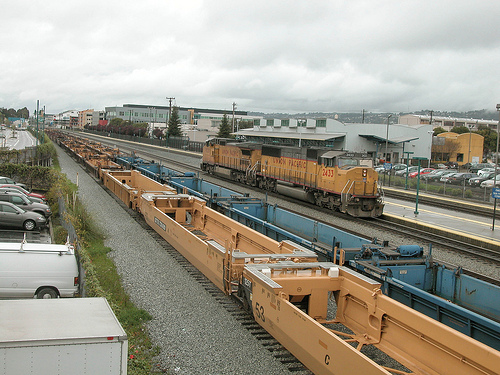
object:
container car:
[137, 195, 318, 292]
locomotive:
[200, 135, 384, 216]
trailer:
[4, 297, 137, 374]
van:
[3, 238, 86, 299]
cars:
[0, 174, 30, 192]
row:
[0, 168, 97, 375]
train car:
[367, 257, 500, 341]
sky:
[10, 3, 497, 111]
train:
[260, 272, 493, 374]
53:
[254, 302, 266, 321]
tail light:
[74, 276, 81, 287]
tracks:
[75, 130, 500, 374]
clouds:
[0, 0, 495, 109]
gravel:
[106, 224, 127, 239]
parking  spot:
[0, 225, 51, 240]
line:
[453, 216, 483, 224]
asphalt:
[388, 192, 498, 240]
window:
[339, 158, 357, 166]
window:
[361, 160, 374, 166]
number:
[322, 169, 334, 178]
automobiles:
[0, 199, 47, 230]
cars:
[409, 167, 437, 180]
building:
[243, 118, 433, 165]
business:
[434, 133, 486, 164]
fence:
[53, 189, 78, 247]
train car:
[99, 164, 168, 205]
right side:
[150, 84, 500, 191]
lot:
[379, 153, 498, 197]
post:
[415, 158, 421, 214]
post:
[403, 150, 410, 189]